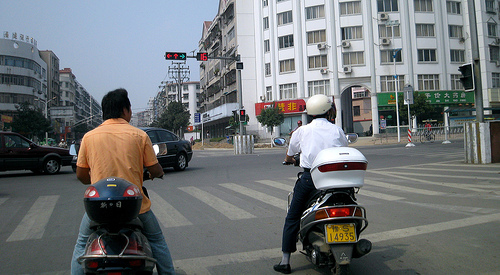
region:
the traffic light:
[132, 29, 230, 74]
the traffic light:
[168, 25, 249, 87]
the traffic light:
[143, 14, 263, 112]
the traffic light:
[145, 46, 222, 86]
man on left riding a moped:
[68, 85, 175, 272]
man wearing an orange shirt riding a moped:
[57, 81, 172, 271]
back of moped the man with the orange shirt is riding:
[78, 221, 159, 272]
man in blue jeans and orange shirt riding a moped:
[50, 85, 175, 270]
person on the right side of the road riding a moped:
[274, 92, 371, 269]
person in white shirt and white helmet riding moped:
[266, 82, 373, 267]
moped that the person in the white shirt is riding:
[306, 146, 366, 266]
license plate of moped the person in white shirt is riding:
[325, 220, 355, 240]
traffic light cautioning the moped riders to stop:
[163, 47, 188, 63]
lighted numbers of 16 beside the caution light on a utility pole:
[197, 51, 212, 61]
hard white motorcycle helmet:
[296, 90, 336, 120]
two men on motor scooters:
[75, 88, 372, 273]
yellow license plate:
[326, 222, 356, 243]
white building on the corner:
[256, 2, 497, 132]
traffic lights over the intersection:
[165, 50, 209, 61]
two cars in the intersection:
[0, 131, 192, 173]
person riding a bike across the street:
[420, 121, 435, 141]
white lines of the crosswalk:
[12, 165, 452, 235]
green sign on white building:
[378, 90, 477, 108]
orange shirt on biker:
[85, 125, 161, 212]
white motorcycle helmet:
[303, 95, 333, 115]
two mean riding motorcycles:
[63, 75, 406, 270]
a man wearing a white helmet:
[300, 80, 353, 145]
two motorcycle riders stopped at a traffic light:
[19, 76, 411, 258]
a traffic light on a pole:
[138, 43, 237, 70]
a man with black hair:
[81, 84, 146, 141]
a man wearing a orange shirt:
[83, 87, 158, 207]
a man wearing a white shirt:
[300, 90, 361, 159]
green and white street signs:
[376, 81, 478, 115]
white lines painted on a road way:
[163, 172, 285, 251]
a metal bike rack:
[400, 117, 458, 149]